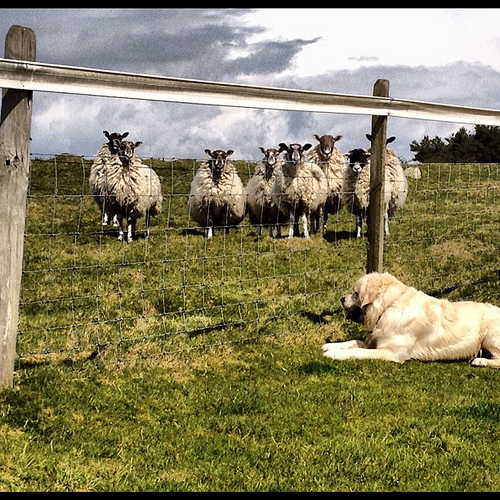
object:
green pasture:
[3, 138, 498, 492]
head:
[102, 130, 130, 153]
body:
[100, 164, 163, 212]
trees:
[430, 134, 454, 159]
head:
[313, 134, 343, 160]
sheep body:
[306, 149, 346, 214]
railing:
[0, 26, 497, 391]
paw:
[322, 351, 334, 360]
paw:
[320, 343, 332, 351]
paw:
[471, 362, 487, 368]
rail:
[0, 58, 499, 131]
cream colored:
[408, 313, 476, 346]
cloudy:
[0, 8, 499, 157]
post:
[367, 78, 390, 274]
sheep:
[188, 134, 410, 240]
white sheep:
[354, 132, 407, 239]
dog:
[321, 271, 500, 370]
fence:
[0, 5, 498, 385]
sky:
[2, 6, 497, 170]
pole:
[0, 25, 40, 395]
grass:
[0, 154, 497, 497]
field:
[0, 148, 497, 497]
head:
[343, 148, 371, 172]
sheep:
[86, 130, 163, 243]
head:
[204, 149, 234, 172]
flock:
[88, 130, 408, 238]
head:
[279, 142, 314, 168]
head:
[111, 139, 143, 162]